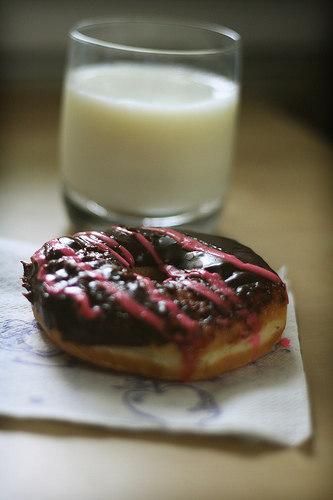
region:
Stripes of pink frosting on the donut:
[39, 226, 278, 355]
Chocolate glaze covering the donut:
[36, 224, 264, 338]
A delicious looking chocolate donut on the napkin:
[24, 205, 294, 411]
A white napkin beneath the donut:
[0, 366, 314, 452]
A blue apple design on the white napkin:
[124, 381, 221, 437]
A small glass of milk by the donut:
[55, 20, 236, 247]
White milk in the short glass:
[51, 64, 255, 220]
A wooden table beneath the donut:
[256, 156, 331, 257]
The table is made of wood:
[4, 101, 61, 225]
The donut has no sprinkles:
[31, 221, 302, 345]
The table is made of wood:
[32, 448, 328, 496]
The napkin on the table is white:
[19, 367, 315, 443]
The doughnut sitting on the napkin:
[24, 223, 317, 458]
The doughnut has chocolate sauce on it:
[31, 220, 294, 374]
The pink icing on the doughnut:
[57, 262, 276, 308]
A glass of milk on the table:
[50, 15, 246, 227]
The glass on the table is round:
[50, 18, 258, 230]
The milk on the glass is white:
[65, 87, 230, 213]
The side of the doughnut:
[92, 304, 296, 374]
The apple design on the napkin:
[115, 376, 224, 427]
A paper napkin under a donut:
[0, 236, 309, 442]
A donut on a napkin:
[19, 223, 284, 375]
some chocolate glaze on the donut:
[14, 227, 281, 340]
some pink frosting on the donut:
[28, 223, 284, 369]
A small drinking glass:
[57, 15, 236, 223]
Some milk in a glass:
[60, 62, 234, 213]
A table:
[0, 83, 332, 493]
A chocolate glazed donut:
[20, 226, 285, 378]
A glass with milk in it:
[54, 14, 237, 223]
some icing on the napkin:
[277, 334, 292, 349]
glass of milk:
[55, 14, 244, 228]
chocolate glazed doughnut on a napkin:
[19, 222, 293, 386]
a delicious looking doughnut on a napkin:
[19, 223, 294, 387]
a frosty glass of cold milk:
[57, 13, 244, 233]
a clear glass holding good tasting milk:
[57, 14, 243, 230]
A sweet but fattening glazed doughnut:
[19, 221, 292, 386]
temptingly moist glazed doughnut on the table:
[20, 224, 294, 386]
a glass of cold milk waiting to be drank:
[54, 12, 248, 230]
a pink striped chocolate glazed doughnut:
[21, 221, 291, 384]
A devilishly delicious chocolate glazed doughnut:
[21, 226, 292, 387]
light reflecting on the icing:
[200, 248, 216, 269]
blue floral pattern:
[122, 389, 233, 431]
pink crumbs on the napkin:
[279, 331, 302, 350]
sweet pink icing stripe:
[66, 246, 92, 275]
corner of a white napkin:
[247, 388, 308, 437]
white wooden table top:
[34, 443, 324, 498]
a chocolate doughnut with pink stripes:
[30, 226, 286, 382]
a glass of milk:
[57, 27, 256, 230]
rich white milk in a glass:
[109, 114, 200, 205]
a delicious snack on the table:
[17, 13, 294, 413]